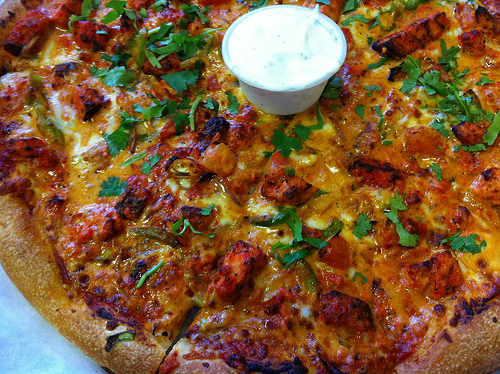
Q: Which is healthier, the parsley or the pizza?
A: The parsley is healthier than the pizza.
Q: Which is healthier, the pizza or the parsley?
A: The parsley is healthier than the pizza.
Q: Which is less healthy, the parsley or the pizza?
A: The pizza is less healthy than the parsley.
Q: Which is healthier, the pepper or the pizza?
A: The pepper is healthier than the pizza.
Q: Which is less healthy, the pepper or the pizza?
A: The pizza is less healthy than the pepper.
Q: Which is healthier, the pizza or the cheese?
A: The cheese is healthier than the pizza.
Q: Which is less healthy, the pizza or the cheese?
A: The pizza is less healthy than the cheese.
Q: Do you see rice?
A: No, there is no rice.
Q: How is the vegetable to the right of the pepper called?
A: The vegetable is parsley.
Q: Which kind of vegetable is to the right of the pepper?
A: The vegetable is parsley.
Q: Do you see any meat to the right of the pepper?
A: No, there is parsley to the right of the pepper.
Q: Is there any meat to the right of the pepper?
A: No, there is parsley to the right of the pepper.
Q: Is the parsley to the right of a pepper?
A: Yes, the parsley is to the right of a pepper.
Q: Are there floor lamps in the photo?
A: No, there are no floor lamps.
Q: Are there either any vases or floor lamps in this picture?
A: No, there are no floor lamps or vases.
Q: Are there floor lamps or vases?
A: No, there are no floor lamps or vases.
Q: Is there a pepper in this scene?
A: Yes, there is a pepper.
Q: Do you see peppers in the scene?
A: Yes, there is a pepper.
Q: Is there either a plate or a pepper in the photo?
A: Yes, there is a pepper.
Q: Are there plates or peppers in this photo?
A: Yes, there is a pepper.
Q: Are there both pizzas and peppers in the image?
A: Yes, there are both a pepper and a pizza.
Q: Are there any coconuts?
A: No, there are no coconuts.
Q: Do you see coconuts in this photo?
A: No, there are no coconuts.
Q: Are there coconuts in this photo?
A: No, there are no coconuts.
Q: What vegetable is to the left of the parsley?
A: The vegetable is a pepper.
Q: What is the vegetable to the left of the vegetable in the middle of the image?
A: The vegetable is a pepper.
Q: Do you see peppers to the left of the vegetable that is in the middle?
A: Yes, there is a pepper to the left of the parsley.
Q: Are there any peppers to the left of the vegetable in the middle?
A: Yes, there is a pepper to the left of the parsley.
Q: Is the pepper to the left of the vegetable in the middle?
A: Yes, the pepper is to the left of the parsley.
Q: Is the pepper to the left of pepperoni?
A: No, the pepper is to the left of the parsley.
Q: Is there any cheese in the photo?
A: Yes, there is cheese.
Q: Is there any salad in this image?
A: No, there is no salad.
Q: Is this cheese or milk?
A: This is cheese.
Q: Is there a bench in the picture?
A: No, there are no benches.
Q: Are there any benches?
A: No, there are no benches.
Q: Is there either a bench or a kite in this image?
A: No, there are no benches or kites.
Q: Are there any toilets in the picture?
A: No, there are no toilets.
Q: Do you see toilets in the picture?
A: No, there are no toilets.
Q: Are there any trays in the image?
A: No, there are no trays.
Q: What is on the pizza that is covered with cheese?
A: The sauce is on the pizza.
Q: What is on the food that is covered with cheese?
A: The sauce is on the pizza.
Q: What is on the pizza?
A: The sauce is on the pizza.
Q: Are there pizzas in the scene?
A: Yes, there is a pizza.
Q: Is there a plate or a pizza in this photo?
A: Yes, there is a pizza.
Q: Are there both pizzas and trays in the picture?
A: No, there is a pizza but no trays.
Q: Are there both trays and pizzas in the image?
A: No, there is a pizza but no trays.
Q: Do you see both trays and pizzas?
A: No, there is a pizza but no trays.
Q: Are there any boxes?
A: No, there are no boxes.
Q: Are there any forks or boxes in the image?
A: No, there are no boxes or forks.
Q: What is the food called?
A: The food is a pizza.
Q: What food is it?
A: The food is a pizza.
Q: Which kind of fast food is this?
A: This is a pizza.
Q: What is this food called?
A: This is a pizza.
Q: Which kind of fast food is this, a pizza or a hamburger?
A: This is a pizza.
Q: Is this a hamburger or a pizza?
A: This is a pizza.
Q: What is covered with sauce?
A: The pizza is covered with sauce.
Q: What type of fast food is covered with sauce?
A: The food is a pizza.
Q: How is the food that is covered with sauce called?
A: The food is a pizza.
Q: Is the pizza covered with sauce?
A: Yes, the pizza is covered with sauce.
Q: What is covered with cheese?
A: The pizza is covered with cheese.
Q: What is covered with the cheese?
A: The pizza is covered with cheese.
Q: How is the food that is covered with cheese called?
A: The food is a pizza.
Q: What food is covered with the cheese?
A: The food is a pizza.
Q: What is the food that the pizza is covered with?
A: The food is cheese.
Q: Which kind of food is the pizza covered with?
A: The pizza is covered with cheese.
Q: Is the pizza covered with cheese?
A: Yes, the pizza is covered with cheese.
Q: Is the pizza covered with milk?
A: No, the pizza is covered with cheese.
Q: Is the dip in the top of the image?
A: Yes, the dip is in the top of the image.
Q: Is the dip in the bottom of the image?
A: No, the dip is in the top of the image.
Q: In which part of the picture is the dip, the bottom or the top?
A: The dip is in the top of the image.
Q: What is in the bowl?
A: The dip is in the bowl.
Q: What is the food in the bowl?
A: The food is a dip.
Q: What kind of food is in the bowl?
A: The food is a dip.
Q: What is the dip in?
A: The dip is in the bowl.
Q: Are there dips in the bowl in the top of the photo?
A: Yes, there is a dip in the bowl.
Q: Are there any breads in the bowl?
A: No, there is a dip in the bowl.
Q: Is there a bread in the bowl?
A: No, there is a dip in the bowl.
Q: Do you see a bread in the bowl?
A: No, there is a dip in the bowl.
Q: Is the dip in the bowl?
A: Yes, the dip is in the bowl.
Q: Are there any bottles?
A: No, there are no bottles.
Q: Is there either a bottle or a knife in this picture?
A: No, there are no bottles or knives.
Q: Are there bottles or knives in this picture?
A: No, there are no bottles or knives.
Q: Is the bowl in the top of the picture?
A: Yes, the bowl is in the top of the image.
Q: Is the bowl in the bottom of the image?
A: No, the bowl is in the top of the image.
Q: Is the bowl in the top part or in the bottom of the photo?
A: The bowl is in the top of the image.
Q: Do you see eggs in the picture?
A: No, there are no eggs.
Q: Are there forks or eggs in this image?
A: No, there are no eggs or forks.